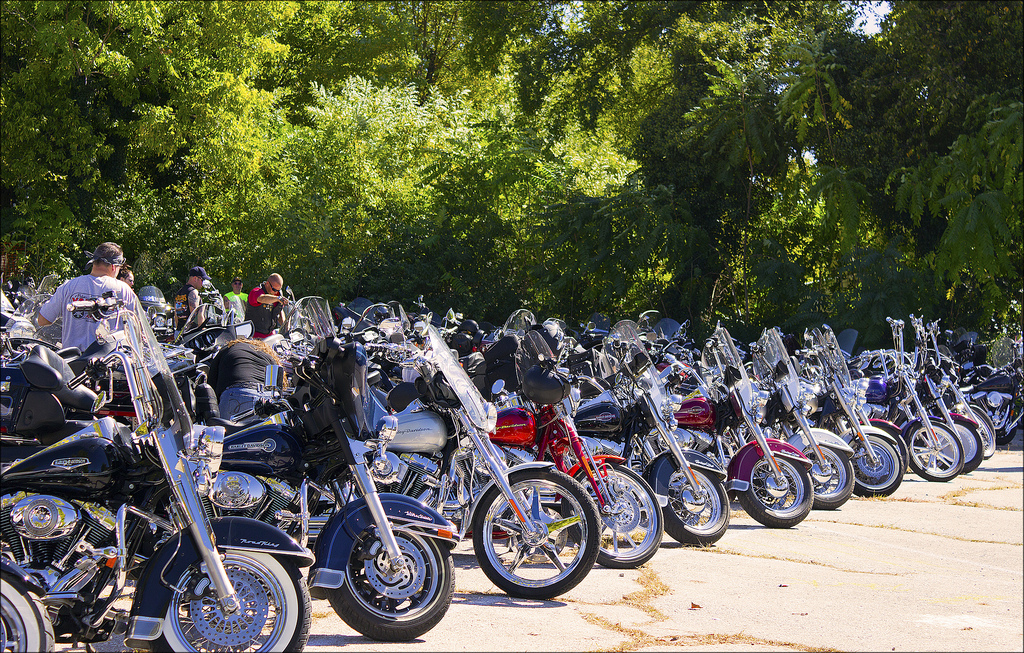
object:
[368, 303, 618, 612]
bike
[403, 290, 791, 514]
row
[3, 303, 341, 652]
bikes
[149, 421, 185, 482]
shiny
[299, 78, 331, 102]
leaves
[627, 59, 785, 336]
tree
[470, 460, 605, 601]
wheel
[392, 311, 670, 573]
motorcycle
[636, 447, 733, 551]
two wheels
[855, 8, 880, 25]
sky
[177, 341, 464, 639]
motorcycles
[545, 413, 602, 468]
fender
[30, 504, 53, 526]
emblem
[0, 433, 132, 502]
gas tank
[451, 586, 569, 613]
shadow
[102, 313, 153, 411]
windshield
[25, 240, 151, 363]
man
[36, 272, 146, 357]
shirt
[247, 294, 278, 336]
vest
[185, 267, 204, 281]
bandana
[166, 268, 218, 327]
people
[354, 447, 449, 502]
motor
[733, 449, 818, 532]
tire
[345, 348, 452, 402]
handlebar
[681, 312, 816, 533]
motorcycle